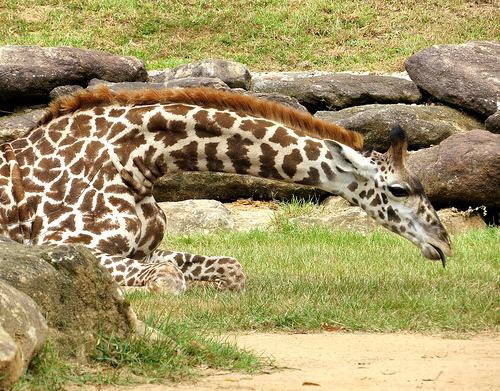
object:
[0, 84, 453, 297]
giraffe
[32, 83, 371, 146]
mane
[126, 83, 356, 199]
neck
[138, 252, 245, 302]
knees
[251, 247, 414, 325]
grass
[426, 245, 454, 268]
tongue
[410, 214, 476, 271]
mouth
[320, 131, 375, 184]
ear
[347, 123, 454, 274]
head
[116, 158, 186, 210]
bottom of neck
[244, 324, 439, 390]
dirt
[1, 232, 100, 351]
rocks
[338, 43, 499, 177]
boulder rocks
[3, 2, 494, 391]
outdoor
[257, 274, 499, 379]
ground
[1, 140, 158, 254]
body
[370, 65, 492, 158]
cluster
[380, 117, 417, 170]
horns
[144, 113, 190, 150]
spots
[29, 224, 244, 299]
legs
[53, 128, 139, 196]
fur